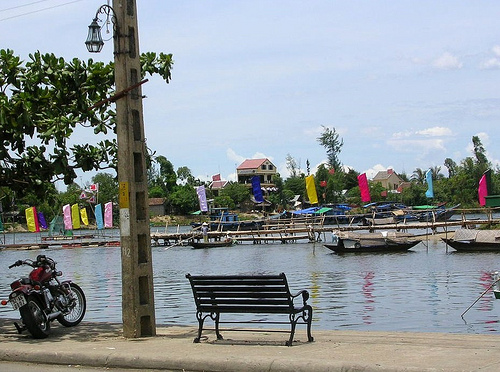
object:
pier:
[207, 206, 500, 238]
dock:
[0, 210, 500, 253]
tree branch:
[0, 50, 175, 204]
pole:
[364, 172, 372, 212]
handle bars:
[7, 255, 59, 272]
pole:
[107, 0, 156, 336]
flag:
[25, 206, 41, 233]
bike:
[0, 253, 86, 339]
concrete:
[1, 317, 497, 372]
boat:
[189, 238, 232, 249]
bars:
[7, 254, 52, 270]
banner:
[104, 201, 113, 229]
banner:
[62, 204, 72, 230]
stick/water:
[161, 232, 194, 252]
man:
[201, 222, 209, 243]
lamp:
[84, 4, 119, 54]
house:
[372, 169, 413, 205]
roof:
[373, 168, 404, 181]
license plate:
[10, 293, 28, 311]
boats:
[323, 227, 500, 251]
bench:
[184, 271, 314, 346]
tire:
[55, 282, 86, 324]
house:
[208, 157, 278, 214]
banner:
[478, 174, 488, 207]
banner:
[424, 169, 435, 198]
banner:
[357, 172, 371, 202]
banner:
[305, 174, 319, 205]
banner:
[251, 176, 265, 202]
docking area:
[1, 200, 500, 254]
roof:
[236, 158, 267, 169]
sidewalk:
[0, 316, 497, 370]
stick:
[460, 272, 500, 318]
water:
[1, 213, 500, 333]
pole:
[68, 204, 74, 240]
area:
[4, 230, 484, 324]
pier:
[0, 216, 500, 252]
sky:
[1, 2, 482, 183]